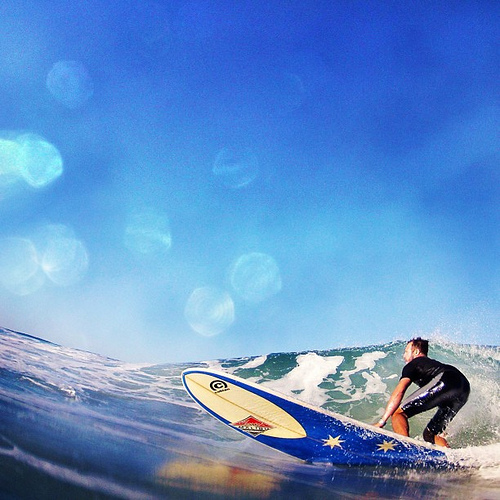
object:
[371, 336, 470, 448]
man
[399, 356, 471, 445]
wetsuit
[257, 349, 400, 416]
foam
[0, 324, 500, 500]
ocean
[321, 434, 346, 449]
star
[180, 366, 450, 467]
surfboard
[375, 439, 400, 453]
star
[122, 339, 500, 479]
wave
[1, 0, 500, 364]
sky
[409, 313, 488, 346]
splash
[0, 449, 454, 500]
reflection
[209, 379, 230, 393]
logo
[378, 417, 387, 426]
watch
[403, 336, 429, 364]
head